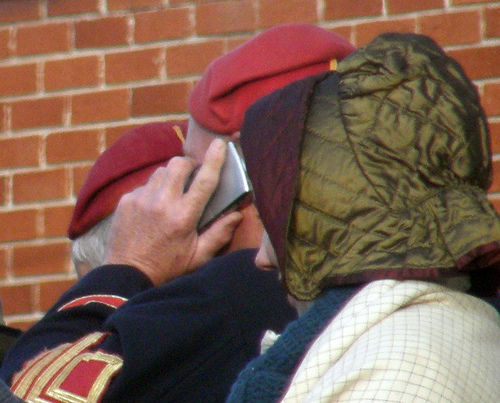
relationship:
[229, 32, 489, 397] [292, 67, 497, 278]
woman wearing hood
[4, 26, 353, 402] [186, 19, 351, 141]
man wearing hat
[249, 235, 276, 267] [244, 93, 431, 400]
nose of a woman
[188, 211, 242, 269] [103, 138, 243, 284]
finger of a hand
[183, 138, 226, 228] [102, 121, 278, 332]
finger on hand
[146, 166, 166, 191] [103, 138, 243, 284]
finger of hand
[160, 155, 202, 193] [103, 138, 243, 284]
finger of hand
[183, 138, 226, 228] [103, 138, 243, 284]
finger of hand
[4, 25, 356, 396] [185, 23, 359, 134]
man wears hat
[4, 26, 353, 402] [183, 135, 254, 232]
man on cell phone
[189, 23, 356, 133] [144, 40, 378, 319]
cap on man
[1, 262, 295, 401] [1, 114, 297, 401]
jacket on man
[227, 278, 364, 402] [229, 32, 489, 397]
blue scarf on woman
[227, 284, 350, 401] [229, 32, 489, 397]
blue scarf on woman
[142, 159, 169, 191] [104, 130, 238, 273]
finger on hand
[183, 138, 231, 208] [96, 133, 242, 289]
finger on hand